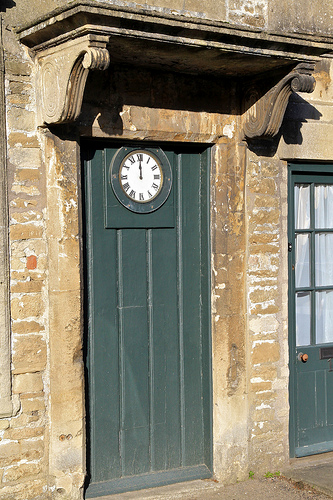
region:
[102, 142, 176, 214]
Old-fashioned looking clock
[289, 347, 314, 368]
Door handle on an old door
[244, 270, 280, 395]
Some bricks on an old building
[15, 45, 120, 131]
Fancy trim on an old door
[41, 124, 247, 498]
A green door with a clock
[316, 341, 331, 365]
A mail slot in a door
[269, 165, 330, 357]
A windowed door with white curtains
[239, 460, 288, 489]
Some grass growing out of a sidewalk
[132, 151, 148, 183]
The hands of an old clock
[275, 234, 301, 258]
A doorbell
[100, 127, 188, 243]
The Clock in the Door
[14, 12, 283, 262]
Clock under the lintel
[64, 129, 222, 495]
Clock in the Green Doorway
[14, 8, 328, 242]
A Beautiful Masonry Ledge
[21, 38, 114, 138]
Handcarved Stone Masonry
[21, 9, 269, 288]
The Clock in the Back Entry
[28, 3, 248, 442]
Blue-Green Doorway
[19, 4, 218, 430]
Stone Masonry At Work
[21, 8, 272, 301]
Clock Under the Mantel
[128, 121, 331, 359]
Unusual Blue Doorways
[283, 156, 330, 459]
the door is green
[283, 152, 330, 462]
the door is shut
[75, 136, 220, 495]
the opening is green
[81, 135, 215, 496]
the opening has a clock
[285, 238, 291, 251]
the door has a doorbell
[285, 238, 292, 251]
the doorbell is black and white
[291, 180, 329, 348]
the door has a white curtain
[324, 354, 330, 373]
a black number 1 is on the door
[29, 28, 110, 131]
the bracket is made of wood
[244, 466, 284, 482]
green plants are next to the building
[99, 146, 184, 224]
A clock with Roman numerals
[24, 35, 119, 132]
A detail over a door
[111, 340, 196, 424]
Part of a green wooden door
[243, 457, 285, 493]
Weeds growing out of cement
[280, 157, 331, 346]
A windowed door with curtains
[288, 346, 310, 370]
A rusty door handle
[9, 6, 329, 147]
A ledge over a door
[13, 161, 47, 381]
Old bricks in a wall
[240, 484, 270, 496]
A gravelly front stoop